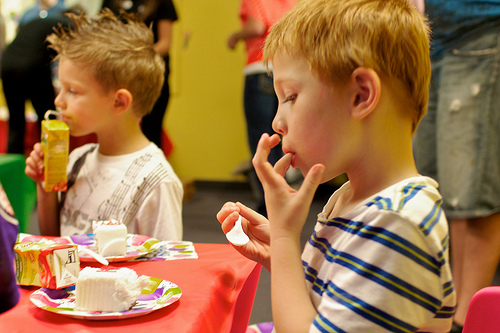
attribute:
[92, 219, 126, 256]
cake — white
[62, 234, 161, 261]
plate — paper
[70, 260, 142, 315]
cake — White 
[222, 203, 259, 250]
spoon — white, plastic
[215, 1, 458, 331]
boy — Eating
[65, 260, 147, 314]
cake — White 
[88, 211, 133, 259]
cake — White 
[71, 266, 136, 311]
white frosting — White 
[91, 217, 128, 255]
white frosting — White 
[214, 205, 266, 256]
spoon — White 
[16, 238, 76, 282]
juice box — Yellow 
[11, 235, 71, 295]
juice box — Discarded 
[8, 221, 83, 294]
juice packet — Yellow 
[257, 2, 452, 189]
hair — Blonde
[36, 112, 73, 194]
juice — Boxed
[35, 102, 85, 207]
juice box — Yellow 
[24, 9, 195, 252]
boy — Eating, drinking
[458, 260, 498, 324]
chair — Red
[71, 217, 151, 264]
cake — White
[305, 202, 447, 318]
shirt — Blue , White 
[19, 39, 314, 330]
kid — drinking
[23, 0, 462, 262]
boys — Eating 